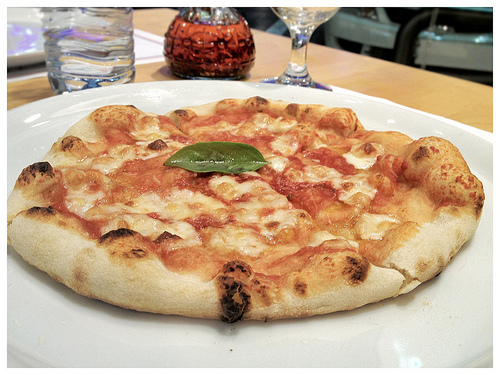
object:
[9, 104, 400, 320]
slice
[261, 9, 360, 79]
goblet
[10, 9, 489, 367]
table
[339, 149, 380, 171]
cheese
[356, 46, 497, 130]
table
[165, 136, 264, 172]
leaf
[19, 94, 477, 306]
pizza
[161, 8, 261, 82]
bottle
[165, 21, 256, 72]
amber liquid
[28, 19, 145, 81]
liquid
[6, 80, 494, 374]
plate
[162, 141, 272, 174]
basil leaf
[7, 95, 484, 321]
pie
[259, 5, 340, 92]
glass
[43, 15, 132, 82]
bottle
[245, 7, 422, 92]
bottle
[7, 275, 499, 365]
plate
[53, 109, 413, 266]
cheese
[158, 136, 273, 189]
basil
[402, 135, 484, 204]
bubbles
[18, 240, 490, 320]
crust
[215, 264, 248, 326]
bubble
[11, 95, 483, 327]
crust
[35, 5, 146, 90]
bottled water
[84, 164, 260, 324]
section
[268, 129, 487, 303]
section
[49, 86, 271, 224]
section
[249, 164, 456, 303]
cut